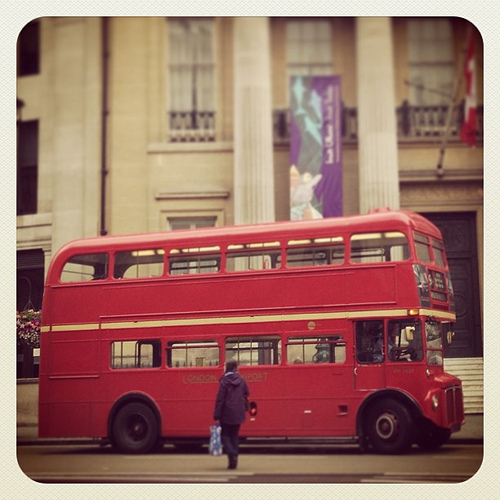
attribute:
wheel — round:
[352, 393, 416, 458]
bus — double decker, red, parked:
[31, 203, 467, 458]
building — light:
[105, 17, 481, 441]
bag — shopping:
[202, 421, 239, 460]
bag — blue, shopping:
[204, 425, 227, 463]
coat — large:
[212, 370, 258, 432]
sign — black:
[427, 264, 454, 300]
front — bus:
[392, 203, 486, 443]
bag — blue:
[200, 408, 233, 468]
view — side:
[40, 205, 468, 465]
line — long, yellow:
[39, 305, 466, 339]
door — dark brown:
[354, 306, 392, 398]